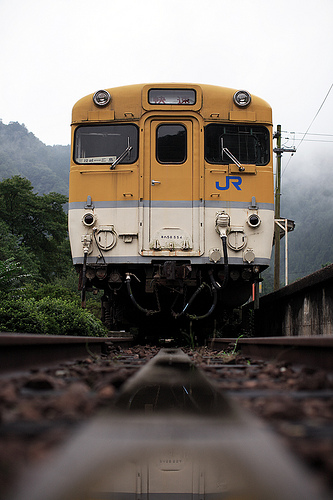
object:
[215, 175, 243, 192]
sign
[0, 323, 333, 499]
tracks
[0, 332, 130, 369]
iron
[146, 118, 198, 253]
door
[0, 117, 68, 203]
mountains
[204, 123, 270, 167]
window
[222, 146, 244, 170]
wiper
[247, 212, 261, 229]
headlight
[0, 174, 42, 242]
trees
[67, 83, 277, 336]
bus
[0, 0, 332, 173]
sky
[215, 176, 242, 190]
letter